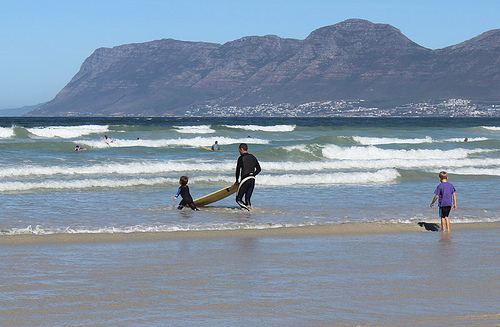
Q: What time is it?
A: Afternoon.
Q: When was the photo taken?
A: During the daytime.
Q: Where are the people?
A: In the water.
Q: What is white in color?
A: Waves.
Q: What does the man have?
A: Board.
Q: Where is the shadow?
A: On the ground.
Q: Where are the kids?
A: Beach.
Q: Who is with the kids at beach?
A: Father.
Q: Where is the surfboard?
A: In water.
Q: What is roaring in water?
A: Waves.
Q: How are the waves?
A: Small.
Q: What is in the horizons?
A: Mountains.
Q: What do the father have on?
A: Wetsuit.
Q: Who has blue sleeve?
A: A little boy.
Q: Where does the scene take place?
A: On a beach.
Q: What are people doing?
A: Surfing.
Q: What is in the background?
A: Mountains.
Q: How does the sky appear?
A: Clear and blue.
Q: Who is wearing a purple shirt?
A: Boy on the right.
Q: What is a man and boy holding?
A: Surfboard.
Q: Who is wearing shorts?
A: Boy in purple shirt.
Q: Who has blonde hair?
A: Boy in purple.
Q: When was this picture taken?
A: During the day.